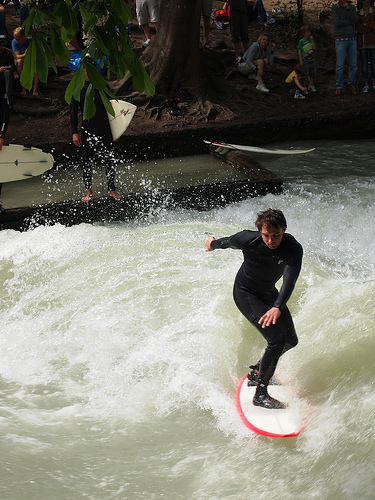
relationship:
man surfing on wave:
[200, 209, 306, 414] [2, 190, 372, 498]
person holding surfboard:
[68, 54, 139, 207] [104, 98, 140, 143]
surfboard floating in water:
[236, 366, 312, 448] [1, 134, 374, 498]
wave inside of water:
[2, 190, 372, 498] [1, 134, 374, 498]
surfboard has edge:
[236, 366, 312, 448] [236, 369, 307, 448]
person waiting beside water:
[68, 54, 139, 207] [1, 134, 374, 498]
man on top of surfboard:
[200, 209, 306, 414] [236, 366, 312, 448]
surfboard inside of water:
[236, 366, 312, 448] [1, 134, 374, 498]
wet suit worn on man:
[209, 231, 300, 383] [200, 209, 306, 414]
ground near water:
[1, 67, 374, 170] [1, 134, 374, 498]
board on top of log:
[199, 133, 323, 163] [201, 136, 284, 193]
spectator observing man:
[323, 4, 364, 102] [200, 209, 306, 414]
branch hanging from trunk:
[0, 5, 161, 135] [100, 2, 231, 126]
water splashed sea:
[1, 134, 374, 498] [8, 203, 358, 476]